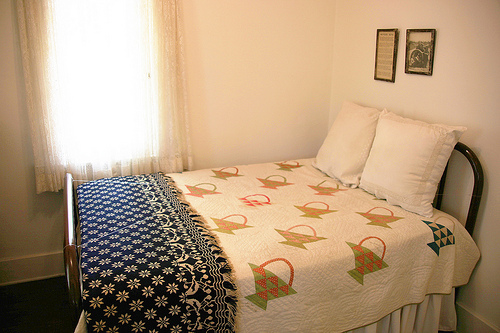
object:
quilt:
[161, 159, 474, 332]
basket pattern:
[273, 224, 328, 250]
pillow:
[361, 107, 465, 217]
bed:
[60, 112, 487, 331]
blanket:
[72, 173, 236, 333]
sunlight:
[48, 2, 160, 166]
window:
[8, 1, 198, 174]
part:
[0, 260, 86, 333]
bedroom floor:
[7, 269, 466, 332]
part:
[189, 12, 307, 90]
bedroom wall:
[6, 2, 328, 287]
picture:
[403, 28, 437, 76]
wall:
[333, 6, 498, 326]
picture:
[373, 28, 400, 84]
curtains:
[17, 0, 199, 192]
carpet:
[0, 267, 77, 333]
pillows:
[312, 100, 385, 187]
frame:
[328, 111, 485, 241]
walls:
[4, 3, 335, 300]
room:
[4, 1, 500, 333]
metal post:
[454, 140, 486, 239]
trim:
[2, 250, 73, 285]